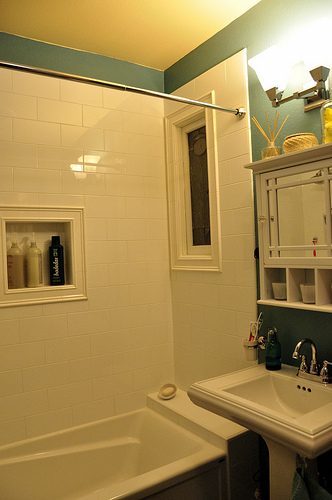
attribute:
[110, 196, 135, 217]
tiles — white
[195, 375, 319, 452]
sink — white, bathroom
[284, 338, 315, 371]
faucet — chrome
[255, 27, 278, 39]
wall — green, beige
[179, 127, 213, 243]
window — white, bathroom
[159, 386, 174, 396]
soap — tan, green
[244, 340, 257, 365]
cup — white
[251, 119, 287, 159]
bottle — clear, shampoo, black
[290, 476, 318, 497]
towel — green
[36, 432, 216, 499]
tub — beige, white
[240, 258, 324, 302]
shelf — small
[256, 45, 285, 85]
light — on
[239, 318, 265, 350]
toothpaste — tube